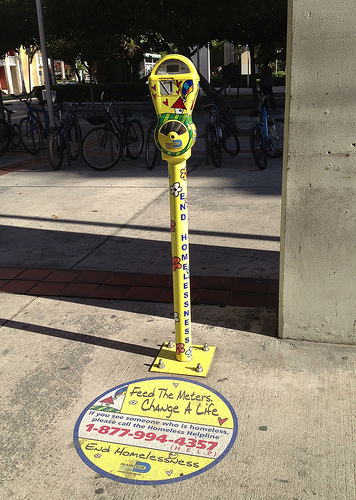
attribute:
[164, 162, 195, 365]
post — cement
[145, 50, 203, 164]
meter — green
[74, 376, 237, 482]
sign — yellow, blue, multi-colored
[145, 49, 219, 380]
meter — yellow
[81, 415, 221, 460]
number — phone number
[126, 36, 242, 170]
meter — parking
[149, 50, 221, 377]
parking meter — yellow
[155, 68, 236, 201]
colored meter — multi-colored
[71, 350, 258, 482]
sign — white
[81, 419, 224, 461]
number — 1-877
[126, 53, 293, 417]
meter — bright, yellow, parking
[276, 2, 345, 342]
pole — thin